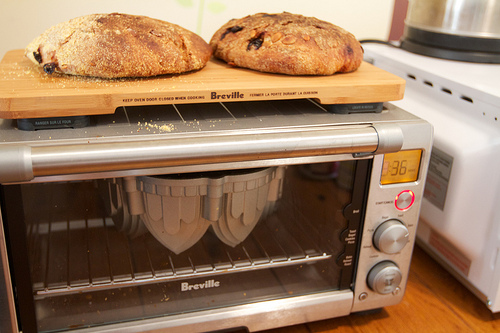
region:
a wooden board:
[3, 51, 404, 110]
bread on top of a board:
[37, 12, 364, 94]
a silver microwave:
[20, 132, 432, 322]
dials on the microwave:
[373, 213, 420, 288]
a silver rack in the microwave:
[33, 251, 339, 279]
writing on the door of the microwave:
[171, 275, 230, 294]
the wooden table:
[413, 285, 464, 330]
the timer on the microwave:
[387, 157, 412, 174]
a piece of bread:
[38, 10, 228, 78]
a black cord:
[361, 30, 391, 51]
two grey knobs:
[371, 227, 410, 292]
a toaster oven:
[10, 152, 405, 322]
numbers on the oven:
[386, 156, 411, 178]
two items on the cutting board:
[28, 14, 367, 71]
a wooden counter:
[413, 297, 455, 327]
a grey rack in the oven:
[111, 272, 154, 284]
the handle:
[138, 138, 308, 153]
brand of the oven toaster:
[176, 278, 226, 295]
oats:
[271, 31, 298, 45]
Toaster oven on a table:
[0, 6, 494, 324]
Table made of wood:
[371, 244, 494, 327]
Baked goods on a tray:
[0, 11, 419, 104]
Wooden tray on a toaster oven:
[1, 62, 409, 123]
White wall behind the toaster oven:
[0, 2, 393, 46]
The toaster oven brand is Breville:
[164, 273, 229, 295]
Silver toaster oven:
[2, 115, 425, 323]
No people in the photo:
[0, 7, 492, 327]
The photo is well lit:
[9, 5, 489, 327]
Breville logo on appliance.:
[175, 278, 237, 295]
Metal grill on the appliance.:
[32, 213, 117, 304]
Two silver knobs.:
[367, 210, 412, 300]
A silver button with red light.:
[391, 185, 419, 215]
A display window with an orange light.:
[379, 149, 426, 188]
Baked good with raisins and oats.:
[209, 8, 370, 79]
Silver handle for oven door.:
[0, 120, 428, 185]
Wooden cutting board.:
[3, 80, 413, 115]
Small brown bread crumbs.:
[128, 118, 181, 135]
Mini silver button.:
[356, 288, 368, 305]